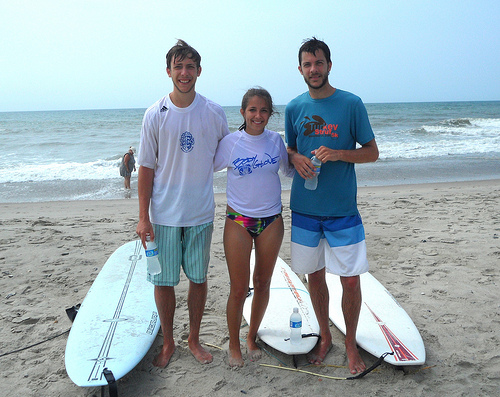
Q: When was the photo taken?
A: Daytime.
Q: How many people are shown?
A: Three.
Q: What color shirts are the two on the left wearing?
A: White.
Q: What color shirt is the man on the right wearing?
A: Blue.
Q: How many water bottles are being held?
A: Two.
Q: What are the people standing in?
A: Sand.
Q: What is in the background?
A: Water.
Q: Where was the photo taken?
A: At a beautiful beach.